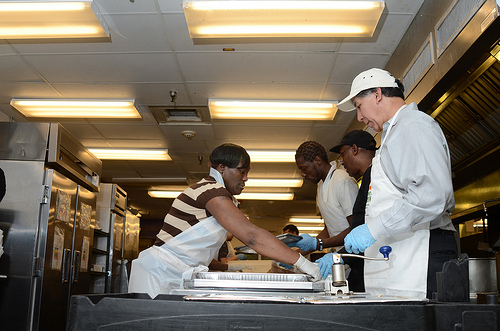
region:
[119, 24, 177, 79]
this is the ceiling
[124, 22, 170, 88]
the ceiling is white in color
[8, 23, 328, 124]
these are four bulbs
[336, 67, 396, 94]
this is a cap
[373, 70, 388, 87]
the cap is white in color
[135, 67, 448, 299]
these are several people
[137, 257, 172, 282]
this is an apron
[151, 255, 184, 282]
the apron is white in color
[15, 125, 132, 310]
these are several fridges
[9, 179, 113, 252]
the fridges are metallic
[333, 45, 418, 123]
the cap is white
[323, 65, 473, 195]
the cap is white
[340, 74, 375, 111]
the cap is white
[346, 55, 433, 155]
the cap is white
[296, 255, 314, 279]
The kitchen worker is wearing latex gloves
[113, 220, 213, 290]
The worker has a plastic apron on.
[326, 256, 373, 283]
a metal can opener.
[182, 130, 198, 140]
A fire alarm.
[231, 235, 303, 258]
A worker is holding a metal tray.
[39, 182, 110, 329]
A metal container for food.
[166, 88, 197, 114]
A fire sprinkler on the ceiling.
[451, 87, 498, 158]
Air vents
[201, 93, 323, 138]
A fluorescent light fixture.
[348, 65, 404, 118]
A man wearing a white cap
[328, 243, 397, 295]
Can opener attached to table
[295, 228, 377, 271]
Hygienic gloves worn by food handlers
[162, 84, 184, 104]
Fixture for fire safety on ceiling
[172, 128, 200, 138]
Smoke alarm attached to ceiling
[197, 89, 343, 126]
Fluorescent lights attached to ceiling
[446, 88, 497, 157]
Vents for exhaust fans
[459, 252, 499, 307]
Large pot sitting on cook top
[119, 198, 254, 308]
Apron worn by food handler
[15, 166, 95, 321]
Doors on a refrigerated unit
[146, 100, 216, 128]
Exhaust vents installed in the ceiling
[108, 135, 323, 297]
woman leaning over the table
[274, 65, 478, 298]
three men standing over a table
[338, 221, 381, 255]
pale blue glove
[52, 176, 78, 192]
light reflecting off the metal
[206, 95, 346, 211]
four long lights on the ceiling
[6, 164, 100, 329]
large stainless steel refrigerator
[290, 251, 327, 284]
white latex gloes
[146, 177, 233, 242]
tan and brown stripes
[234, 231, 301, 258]
thin silver tray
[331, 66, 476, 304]
man wearing a white apron